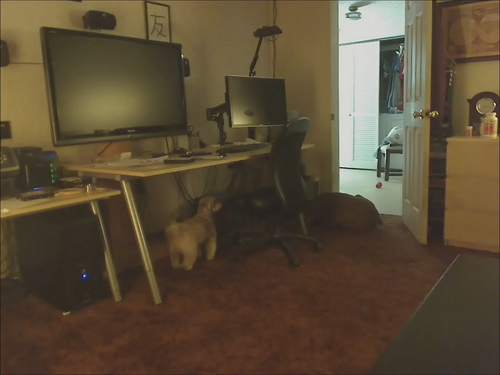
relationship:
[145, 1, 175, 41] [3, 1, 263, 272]
symbol on wall